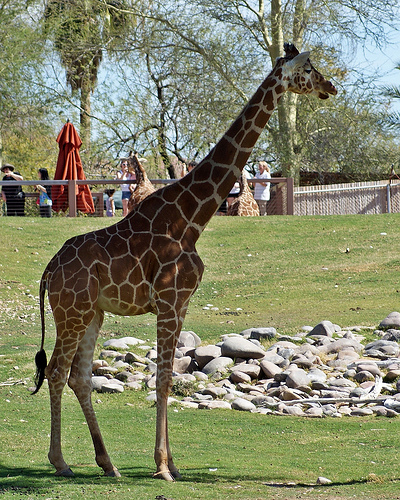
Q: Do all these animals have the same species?
A: Yes, all the animals are giraffes.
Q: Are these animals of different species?
A: No, all the animals are giraffes.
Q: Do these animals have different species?
A: No, all the animals are giraffes.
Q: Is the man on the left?
A: Yes, the man is on the left of the image.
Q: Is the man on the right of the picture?
A: No, the man is on the left of the image.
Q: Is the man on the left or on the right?
A: The man is on the left of the image.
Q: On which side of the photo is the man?
A: The man is on the left of the image.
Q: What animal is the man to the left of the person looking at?
A: The man is looking at the giraffe.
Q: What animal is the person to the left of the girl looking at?
A: The man is looking at the giraffe.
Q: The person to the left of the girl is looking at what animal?
A: The man is looking at the giraffe.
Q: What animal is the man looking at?
A: The man is looking at the giraffe.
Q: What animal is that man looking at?
A: The man is looking at the giraffe.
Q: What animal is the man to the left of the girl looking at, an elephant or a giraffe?
A: The man is looking at a giraffe.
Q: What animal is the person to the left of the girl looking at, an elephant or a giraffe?
A: The man is looking at a giraffe.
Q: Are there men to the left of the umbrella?
A: Yes, there is a man to the left of the umbrella.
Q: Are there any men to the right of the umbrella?
A: No, the man is to the left of the umbrella.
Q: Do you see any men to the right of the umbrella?
A: No, the man is to the left of the umbrella.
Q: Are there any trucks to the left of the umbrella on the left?
A: No, there is a man to the left of the umbrella.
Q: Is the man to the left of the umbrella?
A: Yes, the man is to the left of the umbrella.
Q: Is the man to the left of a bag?
A: No, the man is to the left of the umbrella.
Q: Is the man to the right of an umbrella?
A: No, the man is to the left of an umbrella.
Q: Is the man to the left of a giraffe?
A: Yes, the man is to the left of a giraffe.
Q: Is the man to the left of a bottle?
A: No, the man is to the left of a giraffe.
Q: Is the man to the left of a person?
A: Yes, the man is to the left of a person.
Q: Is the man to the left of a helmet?
A: No, the man is to the left of a person.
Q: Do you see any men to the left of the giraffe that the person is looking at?
A: Yes, there is a man to the left of the giraffe.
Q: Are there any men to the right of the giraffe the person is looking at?
A: No, the man is to the left of the giraffe.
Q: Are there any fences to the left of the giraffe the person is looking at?
A: No, there is a man to the left of the giraffe.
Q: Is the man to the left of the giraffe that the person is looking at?
A: Yes, the man is to the left of the giraffe.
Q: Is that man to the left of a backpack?
A: No, the man is to the left of the giraffe.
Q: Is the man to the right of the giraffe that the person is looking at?
A: No, the man is to the left of the giraffe.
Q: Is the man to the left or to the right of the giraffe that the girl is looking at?
A: The man is to the left of the giraffe.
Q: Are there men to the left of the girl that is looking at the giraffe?
A: Yes, there is a man to the left of the girl.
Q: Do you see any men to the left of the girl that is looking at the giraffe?
A: Yes, there is a man to the left of the girl.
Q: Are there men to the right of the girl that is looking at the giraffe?
A: No, the man is to the left of the girl.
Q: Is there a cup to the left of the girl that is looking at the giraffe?
A: No, there is a man to the left of the girl.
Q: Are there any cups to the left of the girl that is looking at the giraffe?
A: No, there is a man to the left of the girl.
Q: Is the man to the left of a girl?
A: Yes, the man is to the left of a girl.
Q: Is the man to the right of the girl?
A: No, the man is to the left of the girl.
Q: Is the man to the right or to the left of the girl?
A: The man is to the left of the girl.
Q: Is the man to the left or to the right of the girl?
A: The man is to the left of the girl.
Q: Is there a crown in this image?
A: No, there are no crowns.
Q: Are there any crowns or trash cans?
A: No, there are no crowns or trash cans.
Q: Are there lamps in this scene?
A: No, there are no lamps.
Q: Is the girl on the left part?
A: Yes, the girl is on the left of the image.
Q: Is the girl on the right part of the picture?
A: No, the girl is on the left of the image.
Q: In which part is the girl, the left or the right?
A: The girl is on the left of the image.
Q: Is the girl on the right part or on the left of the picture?
A: The girl is on the left of the image.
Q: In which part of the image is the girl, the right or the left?
A: The girl is on the left of the image.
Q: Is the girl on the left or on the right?
A: The girl is on the left of the image.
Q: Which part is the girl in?
A: The girl is on the left of the image.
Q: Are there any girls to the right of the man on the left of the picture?
A: Yes, there is a girl to the right of the man.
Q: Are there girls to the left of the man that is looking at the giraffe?
A: No, the girl is to the right of the man.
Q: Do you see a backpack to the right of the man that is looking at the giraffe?
A: No, there is a girl to the right of the man.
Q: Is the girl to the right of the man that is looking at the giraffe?
A: Yes, the girl is to the right of the man.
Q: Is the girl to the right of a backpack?
A: No, the girl is to the right of the man.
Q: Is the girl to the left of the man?
A: No, the girl is to the right of the man.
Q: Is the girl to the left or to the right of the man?
A: The girl is to the right of the man.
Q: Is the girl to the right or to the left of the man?
A: The girl is to the right of the man.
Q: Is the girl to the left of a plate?
A: No, the girl is to the left of the giraffe.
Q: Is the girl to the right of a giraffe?
A: No, the girl is to the left of a giraffe.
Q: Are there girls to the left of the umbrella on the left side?
A: Yes, there is a girl to the left of the umbrella.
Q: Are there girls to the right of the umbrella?
A: No, the girl is to the left of the umbrella.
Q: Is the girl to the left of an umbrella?
A: Yes, the girl is to the left of an umbrella.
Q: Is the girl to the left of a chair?
A: No, the girl is to the left of an umbrella.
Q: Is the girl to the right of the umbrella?
A: No, the girl is to the left of the umbrella.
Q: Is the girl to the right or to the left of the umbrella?
A: The girl is to the left of the umbrella.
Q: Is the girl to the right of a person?
A: No, the girl is to the left of a person.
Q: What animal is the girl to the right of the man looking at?
A: The girl is looking at the giraffe.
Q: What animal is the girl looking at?
A: The girl is looking at the giraffe.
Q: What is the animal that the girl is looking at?
A: The animal is a giraffe.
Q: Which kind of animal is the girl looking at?
A: The girl is looking at the giraffe.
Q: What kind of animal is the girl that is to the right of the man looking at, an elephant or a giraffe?
A: The girl is looking at a giraffe.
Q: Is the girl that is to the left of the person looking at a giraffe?
A: Yes, the girl is looking at a giraffe.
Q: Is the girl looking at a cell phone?
A: No, the girl is looking at a giraffe.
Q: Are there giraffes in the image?
A: Yes, there is a giraffe.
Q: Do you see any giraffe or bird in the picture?
A: Yes, there is a giraffe.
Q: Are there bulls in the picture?
A: No, there are no bulls.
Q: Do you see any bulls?
A: No, there are no bulls.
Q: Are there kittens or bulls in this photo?
A: No, there are no bulls or kittens.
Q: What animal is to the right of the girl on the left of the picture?
A: The animal is a giraffe.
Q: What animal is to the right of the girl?
A: The animal is a giraffe.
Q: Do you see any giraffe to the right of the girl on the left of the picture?
A: Yes, there is a giraffe to the right of the girl.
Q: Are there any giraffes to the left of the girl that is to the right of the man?
A: No, the giraffe is to the right of the girl.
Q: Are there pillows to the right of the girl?
A: No, there is a giraffe to the right of the girl.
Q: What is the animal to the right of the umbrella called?
A: The animal is a giraffe.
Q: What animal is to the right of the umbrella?
A: The animal is a giraffe.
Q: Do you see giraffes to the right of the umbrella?
A: Yes, there is a giraffe to the right of the umbrella.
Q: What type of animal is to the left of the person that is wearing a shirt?
A: The animal is a giraffe.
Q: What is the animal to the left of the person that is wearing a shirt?
A: The animal is a giraffe.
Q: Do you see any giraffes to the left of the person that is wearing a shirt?
A: Yes, there is a giraffe to the left of the person.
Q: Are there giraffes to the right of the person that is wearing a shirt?
A: No, the giraffe is to the left of the person.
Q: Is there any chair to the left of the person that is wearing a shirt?
A: No, there is a giraffe to the left of the person.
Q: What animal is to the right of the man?
A: The animal is a giraffe.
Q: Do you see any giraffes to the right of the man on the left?
A: Yes, there is a giraffe to the right of the man.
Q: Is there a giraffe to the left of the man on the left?
A: No, the giraffe is to the right of the man.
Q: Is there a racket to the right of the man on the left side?
A: No, there is a giraffe to the right of the man.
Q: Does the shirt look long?
A: Yes, the shirt is long.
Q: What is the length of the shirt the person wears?
A: The shirt is long.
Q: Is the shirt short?
A: No, the shirt is long.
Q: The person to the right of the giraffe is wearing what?
A: The person is wearing a shirt.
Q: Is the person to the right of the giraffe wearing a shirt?
A: Yes, the person is wearing a shirt.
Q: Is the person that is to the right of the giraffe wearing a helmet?
A: No, the person is wearing a shirt.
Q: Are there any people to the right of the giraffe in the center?
A: Yes, there is a person to the right of the giraffe.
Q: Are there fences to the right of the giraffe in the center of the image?
A: No, there is a person to the right of the giraffe.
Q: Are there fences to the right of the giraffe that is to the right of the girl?
A: No, there is a person to the right of the giraffe.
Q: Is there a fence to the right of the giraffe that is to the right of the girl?
A: No, there is a person to the right of the giraffe.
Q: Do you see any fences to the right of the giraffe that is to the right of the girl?
A: No, there is a person to the right of the giraffe.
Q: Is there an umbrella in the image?
A: Yes, there is an umbrella.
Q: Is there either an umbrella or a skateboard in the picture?
A: Yes, there is an umbrella.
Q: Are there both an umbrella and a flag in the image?
A: No, there is an umbrella but no flags.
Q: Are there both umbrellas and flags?
A: No, there is an umbrella but no flags.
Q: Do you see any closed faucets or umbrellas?
A: Yes, there is a closed umbrella.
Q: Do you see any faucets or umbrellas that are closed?
A: Yes, the umbrella is closed.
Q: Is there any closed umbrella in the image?
A: Yes, there is a closed umbrella.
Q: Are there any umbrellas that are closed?
A: Yes, there is an umbrella that is closed.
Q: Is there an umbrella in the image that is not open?
A: Yes, there is an closed umbrella.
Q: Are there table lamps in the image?
A: No, there are no table lamps.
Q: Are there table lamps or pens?
A: No, there are no table lamps or pens.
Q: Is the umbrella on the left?
A: Yes, the umbrella is on the left of the image.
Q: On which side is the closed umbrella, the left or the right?
A: The umbrella is on the left of the image.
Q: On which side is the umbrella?
A: The umbrella is on the left of the image.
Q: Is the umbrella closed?
A: Yes, the umbrella is closed.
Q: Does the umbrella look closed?
A: Yes, the umbrella is closed.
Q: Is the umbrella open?
A: No, the umbrella is closed.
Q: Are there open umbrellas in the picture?
A: No, there is an umbrella but it is closed.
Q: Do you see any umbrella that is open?
A: No, there is an umbrella but it is closed.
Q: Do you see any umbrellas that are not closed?
A: No, there is an umbrella but it is closed.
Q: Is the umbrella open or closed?
A: The umbrella is closed.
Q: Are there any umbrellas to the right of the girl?
A: Yes, there is an umbrella to the right of the girl.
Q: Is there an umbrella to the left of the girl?
A: No, the umbrella is to the right of the girl.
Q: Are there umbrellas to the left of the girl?
A: No, the umbrella is to the right of the girl.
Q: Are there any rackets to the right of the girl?
A: No, there is an umbrella to the right of the girl.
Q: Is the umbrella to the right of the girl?
A: Yes, the umbrella is to the right of the girl.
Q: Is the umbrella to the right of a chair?
A: No, the umbrella is to the right of the girl.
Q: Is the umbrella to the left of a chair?
A: No, the umbrella is to the left of the giraffe.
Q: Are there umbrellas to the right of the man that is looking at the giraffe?
A: Yes, there is an umbrella to the right of the man.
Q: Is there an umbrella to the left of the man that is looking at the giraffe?
A: No, the umbrella is to the right of the man.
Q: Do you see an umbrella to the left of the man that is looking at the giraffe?
A: No, the umbrella is to the right of the man.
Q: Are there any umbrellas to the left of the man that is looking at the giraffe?
A: No, the umbrella is to the right of the man.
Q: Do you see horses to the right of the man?
A: No, there is an umbrella to the right of the man.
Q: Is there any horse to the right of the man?
A: No, there is an umbrella to the right of the man.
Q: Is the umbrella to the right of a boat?
A: No, the umbrella is to the right of a man.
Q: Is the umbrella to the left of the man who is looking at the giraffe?
A: No, the umbrella is to the right of the man.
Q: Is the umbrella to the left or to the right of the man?
A: The umbrella is to the right of the man.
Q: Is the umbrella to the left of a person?
A: Yes, the umbrella is to the left of a person.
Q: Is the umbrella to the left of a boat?
A: No, the umbrella is to the left of a person.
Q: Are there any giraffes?
A: Yes, there is a giraffe.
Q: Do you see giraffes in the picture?
A: Yes, there is a giraffe.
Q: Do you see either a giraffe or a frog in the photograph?
A: Yes, there is a giraffe.